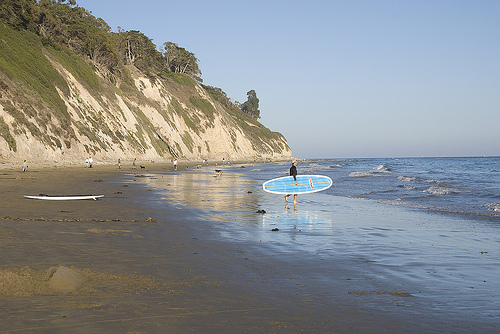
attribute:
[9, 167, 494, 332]
beach — nice, sandy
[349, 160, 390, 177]
wave — white, little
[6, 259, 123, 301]
sand — loose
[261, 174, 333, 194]
surfboard — blue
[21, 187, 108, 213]
surfboard — white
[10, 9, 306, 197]
grass — green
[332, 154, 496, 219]
waves — rolling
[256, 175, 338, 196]
surfboard — blue, white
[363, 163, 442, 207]
waves — white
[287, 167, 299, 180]
wetsuit — black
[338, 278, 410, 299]
beach — wet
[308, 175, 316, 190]
symbol — little, orange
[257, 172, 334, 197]
surfboard — blue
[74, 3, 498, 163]
sky — blue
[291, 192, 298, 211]
leg — bare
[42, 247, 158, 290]
sand — brown, small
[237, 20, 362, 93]
sky — clear blue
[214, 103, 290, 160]
slope — steep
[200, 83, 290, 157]
slope — steep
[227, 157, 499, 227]
ocean — blue